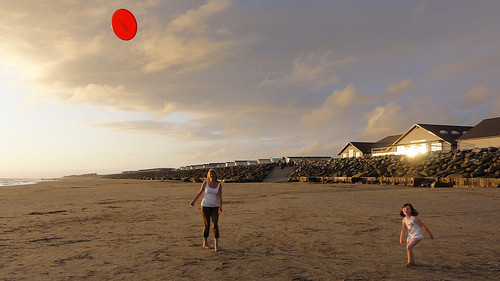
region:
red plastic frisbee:
[107, 3, 141, 47]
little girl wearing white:
[390, 197, 441, 273]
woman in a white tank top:
[187, 165, 225, 255]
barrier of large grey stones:
[109, 148, 498, 197]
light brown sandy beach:
[0, 172, 496, 278]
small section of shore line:
[0, 173, 60, 188]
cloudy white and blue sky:
[0, 0, 498, 187]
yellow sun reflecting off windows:
[385, 135, 451, 160]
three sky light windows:
[434, 122, 474, 139]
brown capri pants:
[195, 200, 225, 242]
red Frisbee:
[98, 12, 133, 50]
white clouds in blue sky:
[380, 52, 421, 86]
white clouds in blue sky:
[185, 39, 219, 89]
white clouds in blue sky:
[18, 31, 98, 108]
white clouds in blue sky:
[48, 92, 108, 143]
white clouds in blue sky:
[205, 86, 250, 140]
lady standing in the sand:
[187, 160, 226, 259]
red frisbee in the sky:
[105, 4, 144, 44]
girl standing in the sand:
[390, 197, 432, 268]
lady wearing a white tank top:
[185, 167, 225, 258]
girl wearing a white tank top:
[393, 200, 435, 273]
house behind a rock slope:
[330, 116, 468, 161]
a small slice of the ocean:
[0, 172, 58, 193]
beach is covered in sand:
[2, 174, 498, 280]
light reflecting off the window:
[401, 139, 431, 156]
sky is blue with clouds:
[0, 3, 496, 185]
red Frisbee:
[100, 6, 141, 46]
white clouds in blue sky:
[17, 22, 52, 56]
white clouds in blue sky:
[74, 96, 106, 117]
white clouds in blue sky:
[234, 35, 265, 69]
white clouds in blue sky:
[172, 31, 230, 89]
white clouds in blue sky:
[255, 76, 289, 97]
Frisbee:
[98, 2, 180, 63]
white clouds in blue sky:
[205, 28, 260, 70]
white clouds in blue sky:
[342, 16, 399, 54]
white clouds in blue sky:
[45, 93, 83, 118]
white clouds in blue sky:
[152, 43, 209, 94]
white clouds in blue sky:
[297, 32, 347, 73]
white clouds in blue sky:
[430, 35, 481, 63]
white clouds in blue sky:
[87, 125, 162, 157]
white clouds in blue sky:
[37, 18, 85, 58]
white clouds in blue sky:
[221, 56, 256, 118]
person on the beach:
[377, 197, 470, 278]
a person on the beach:
[156, 156, 233, 279]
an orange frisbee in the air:
[106, 4, 158, 48]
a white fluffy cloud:
[244, 27, 264, 64]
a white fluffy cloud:
[331, 68, 341, 97]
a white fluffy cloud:
[375, 93, 407, 127]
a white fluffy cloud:
[470, 71, 498, 112]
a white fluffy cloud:
[109, 90, 169, 113]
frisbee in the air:
[102, 3, 153, 51]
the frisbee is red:
[105, 3, 149, 50]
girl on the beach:
[389, 196, 441, 265]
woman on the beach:
[186, 158, 244, 255]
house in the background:
[329, 118, 497, 155]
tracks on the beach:
[19, 168, 396, 280]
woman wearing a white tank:
[192, 178, 233, 216]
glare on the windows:
[390, 139, 427, 157]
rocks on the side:
[286, 151, 485, 182]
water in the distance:
[2, 168, 34, 193]